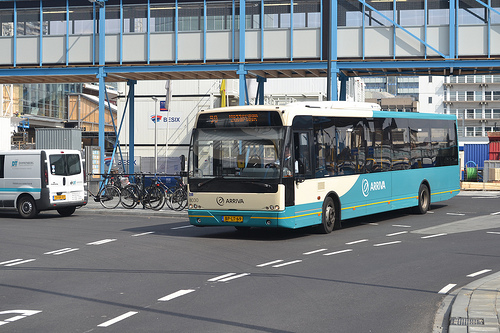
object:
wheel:
[318, 191, 344, 232]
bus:
[182, 104, 468, 229]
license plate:
[215, 214, 248, 228]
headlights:
[183, 199, 283, 237]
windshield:
[191, 123, 287, 185]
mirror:
[174, 150, 190, 185]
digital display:
[199, 112, 266, 130]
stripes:
[77, 228, 440, 328]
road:
[9, 179, 498, 326]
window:
[20, 83, 73, 115]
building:
[4, 11, 118, 185]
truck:
[1, 145, 92, 221]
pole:
[213, 78, 234, 109]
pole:
[323, 68, 346, 106]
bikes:
[89, 168, 197, 212]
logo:
[355, 178, 374, 206]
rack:
[83, 171, 189, 193]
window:
[302, 121, 460, 167]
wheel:
[16, 195, 45, 219]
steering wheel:
[261, 157, 285, 177]